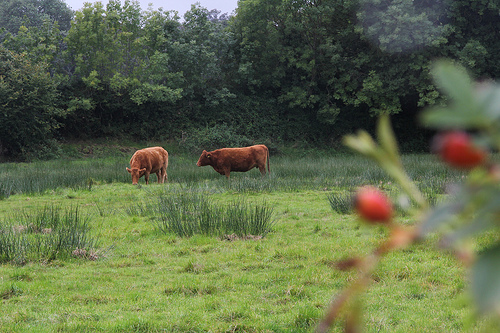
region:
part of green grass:
[96, 238, 250, 313]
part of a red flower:
[366, 182, 396, 222]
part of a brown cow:
[200, 141, 285, 175]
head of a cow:
[126, 159, 146, 187]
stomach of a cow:
[228, 150, 250, 172]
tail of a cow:
[266, 157, 272, 172]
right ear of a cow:
[121, 160, 131, 170]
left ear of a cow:
[135, 165, 148, 175]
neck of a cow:
[206, 157, 221, 173]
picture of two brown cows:
[108, 125, 285, 196]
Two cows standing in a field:
[104, 136, 272, 205]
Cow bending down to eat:
[111, 97, 180, 210]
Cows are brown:
[93, 140, 316, 232]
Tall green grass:
[0, 198, 330, 263]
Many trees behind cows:
[37, 25, 424, 107]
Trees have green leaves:
[31, 23, 357, 126]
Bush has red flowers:
[336, 122, 453, 309]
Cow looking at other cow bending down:
[181, 103, 311, 215]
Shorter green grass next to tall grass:
[112, 240, 266, 328]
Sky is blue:
[58, 4, 220, 21]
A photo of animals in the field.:
[0, 0, 496, 330]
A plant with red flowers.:
[315, 57, 496, 327]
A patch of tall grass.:
[141, 176, 277, 241]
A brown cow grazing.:
[120, 145, 166, 182]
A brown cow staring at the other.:
[195, 141, 270, 173]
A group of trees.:
[0, 0, 496, 132]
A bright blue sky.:
[152, 3, 227, 13]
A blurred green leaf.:
[419, 58, 495, 127]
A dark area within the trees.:
[56, 115, 143, 143]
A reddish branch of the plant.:
[310, 222, 417, 332]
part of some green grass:
[152, 221, 277, 314]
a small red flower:
[355, 175, 394, 240]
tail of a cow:
[263, 148, 273, 169]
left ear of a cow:
[138, 167, 145, 171]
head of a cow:
[195, 148, 215, 170]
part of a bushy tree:
[263, 1, 398, 83]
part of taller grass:
[173, 200, 230, 235]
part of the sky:
[161, 0, 193, 16]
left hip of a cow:
[259, 155, 266, 172]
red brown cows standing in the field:
[195, 145, 272, 176]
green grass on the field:
[138, 191, 284, 241]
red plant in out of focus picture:
[348, 175, 401, 232]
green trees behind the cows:
[0, 0, 498, 127]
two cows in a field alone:
[125, 145, 275, 185]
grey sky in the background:
[56, 0, 237, 21]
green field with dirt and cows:
[0, 177, 495, 330]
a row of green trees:
[5, 23, 495, 144]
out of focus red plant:
[315, 55, 496, 327]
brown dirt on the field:
[217, 231, 263, 241]